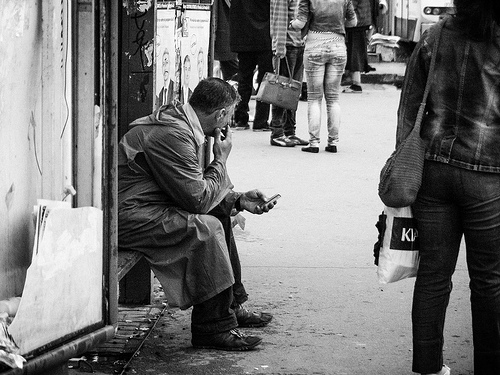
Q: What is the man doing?
A: Sitting.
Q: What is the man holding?
A: A phone and cigarrette.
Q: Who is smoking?
A: A man.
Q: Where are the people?
A: At the sidewalk.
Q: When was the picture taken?
A: Daytime.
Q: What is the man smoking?
A: Cigarrette.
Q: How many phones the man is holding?
A: One.